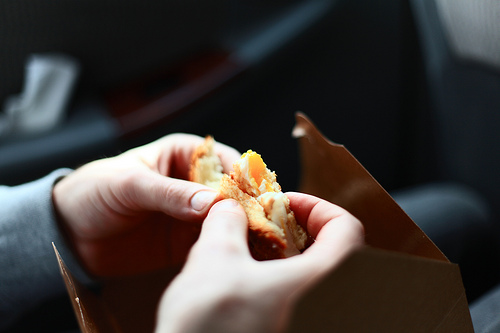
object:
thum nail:
[188, 186, 219, 212]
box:
[285, 111, 474, 333]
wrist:
[0, 168, 69, 304]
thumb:
[185, 191, 257, 271]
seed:
[267, 239, 286, 249]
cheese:
[248, 155, 258, 176]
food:
[183, 137, 303, 260]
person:
[0, 131, 366, 333]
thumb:
[119, 170, 223, 223]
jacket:
[0, 168, 96, 315]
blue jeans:
[421, 184, 484, 233]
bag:
[51, 112, 474, 333]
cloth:
[4, 47, 81, 132]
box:
[2, 124, 48, 175]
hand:
[59, 132, 365, 333]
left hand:
[52, 130, 249, 285]